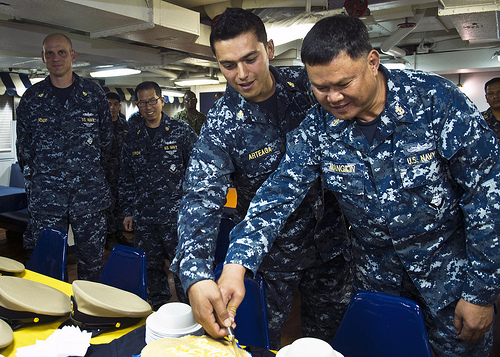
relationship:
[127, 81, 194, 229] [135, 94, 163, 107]
man wearing glasses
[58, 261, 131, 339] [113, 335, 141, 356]
hats on table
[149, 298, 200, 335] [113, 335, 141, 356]
bowl on table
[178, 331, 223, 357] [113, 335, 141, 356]
cake on table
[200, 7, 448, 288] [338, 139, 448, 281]
men in uniform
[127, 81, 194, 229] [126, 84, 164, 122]
man has head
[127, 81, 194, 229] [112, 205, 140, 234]
man has hand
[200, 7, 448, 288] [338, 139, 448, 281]
men wearing uniform